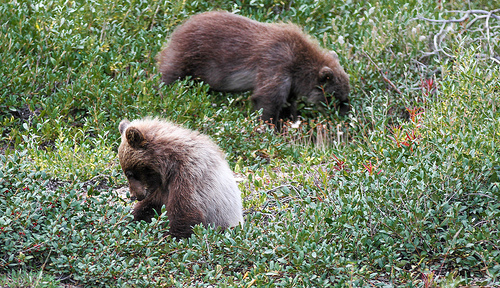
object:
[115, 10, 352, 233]
two baby bears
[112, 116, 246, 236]
bear baby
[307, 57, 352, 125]
bears face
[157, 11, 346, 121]
fur is brown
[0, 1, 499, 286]
green vegetation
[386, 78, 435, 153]
red color flowers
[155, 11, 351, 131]
bear is eating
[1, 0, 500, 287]
day time picture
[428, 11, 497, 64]
twig is brown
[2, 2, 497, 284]
outside scene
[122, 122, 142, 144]
brown ear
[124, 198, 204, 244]
legs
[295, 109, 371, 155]
plants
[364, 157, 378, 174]
tip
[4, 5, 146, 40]
blackground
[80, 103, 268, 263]
plants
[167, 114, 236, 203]
sunlight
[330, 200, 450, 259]
plants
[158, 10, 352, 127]
bear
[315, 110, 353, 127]
nose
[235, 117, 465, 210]
ground